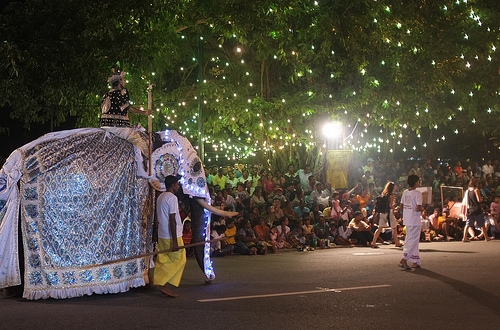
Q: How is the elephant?
A: With the costume.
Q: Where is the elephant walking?
A: On street.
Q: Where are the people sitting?
A: Sidewalk.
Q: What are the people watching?
A: Parade.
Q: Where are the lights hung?
A: Tree.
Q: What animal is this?
A: Elephant.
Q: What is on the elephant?
A: Cloth.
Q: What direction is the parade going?
A: Right.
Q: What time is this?
A: During nighttime.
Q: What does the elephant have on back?
A: A person.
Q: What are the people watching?
A: Parade.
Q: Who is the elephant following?
A: The elephant is following someone.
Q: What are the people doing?
A: Enjoying their evening.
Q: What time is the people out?
A: They are out at night.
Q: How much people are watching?
A: Many people is watching.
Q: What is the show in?
A: In the middle of night.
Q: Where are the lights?
A: In the trees.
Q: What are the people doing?
A: They are sitting.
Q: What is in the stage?
A: An elephant.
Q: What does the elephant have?
A: A blanket.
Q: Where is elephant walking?
A: In parade.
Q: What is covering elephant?
A: Costume.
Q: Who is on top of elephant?
A: Handler.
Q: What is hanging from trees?
A: Lights.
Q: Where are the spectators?
A: On side of parade route.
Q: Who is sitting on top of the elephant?
A: A man.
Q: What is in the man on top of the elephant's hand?
A: A staff.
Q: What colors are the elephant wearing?
A: White, blue, and gold.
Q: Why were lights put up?
A: Because it's dark.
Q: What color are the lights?
A: White.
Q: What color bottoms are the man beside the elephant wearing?
A: Yellow.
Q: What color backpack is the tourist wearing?
A: Black.